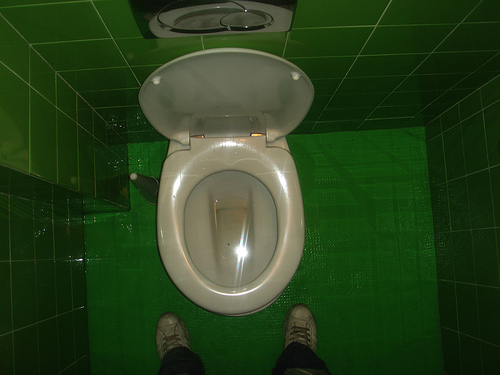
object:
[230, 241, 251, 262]
glare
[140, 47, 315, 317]
toilet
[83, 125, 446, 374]
tiled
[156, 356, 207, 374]
leg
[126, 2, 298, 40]
paper dispenser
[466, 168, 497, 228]
tile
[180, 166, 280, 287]
bowl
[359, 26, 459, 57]
tile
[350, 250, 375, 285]
floor tiles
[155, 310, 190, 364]
shoe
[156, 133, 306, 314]
seat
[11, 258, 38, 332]
tile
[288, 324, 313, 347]
shoelaces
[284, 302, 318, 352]
shoe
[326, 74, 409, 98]
tile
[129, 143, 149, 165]
tile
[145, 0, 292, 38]
mirror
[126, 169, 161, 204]
brush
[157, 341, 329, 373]
blue jeans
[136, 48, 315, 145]
lid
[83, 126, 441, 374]
floor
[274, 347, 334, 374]
leg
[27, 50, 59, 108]
tile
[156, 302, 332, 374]
person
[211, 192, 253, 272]
water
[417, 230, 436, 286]
item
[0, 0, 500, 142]
wall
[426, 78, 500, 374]
wall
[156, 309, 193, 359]
feet